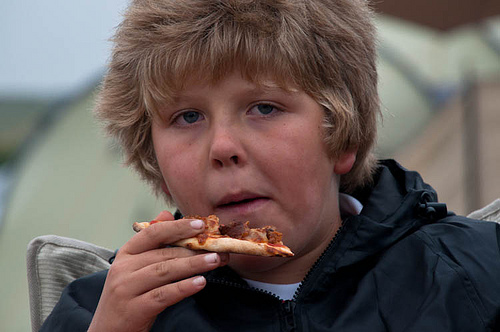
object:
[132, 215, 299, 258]
crust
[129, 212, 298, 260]
pizza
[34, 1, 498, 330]
boy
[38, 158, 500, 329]
windbreaker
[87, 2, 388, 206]
hair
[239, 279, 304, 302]
shirt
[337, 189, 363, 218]
collar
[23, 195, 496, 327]
chair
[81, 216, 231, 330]
hand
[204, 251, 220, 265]
fingernails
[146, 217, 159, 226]
pepperoni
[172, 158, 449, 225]
hood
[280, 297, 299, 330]
pull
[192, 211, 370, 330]
zipper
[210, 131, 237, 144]
freckles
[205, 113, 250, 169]
nose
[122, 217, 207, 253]
finger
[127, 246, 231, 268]
finger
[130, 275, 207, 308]
finger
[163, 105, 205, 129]
eye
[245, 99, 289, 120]
eye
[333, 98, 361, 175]
ear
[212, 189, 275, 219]
mouth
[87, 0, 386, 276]
head